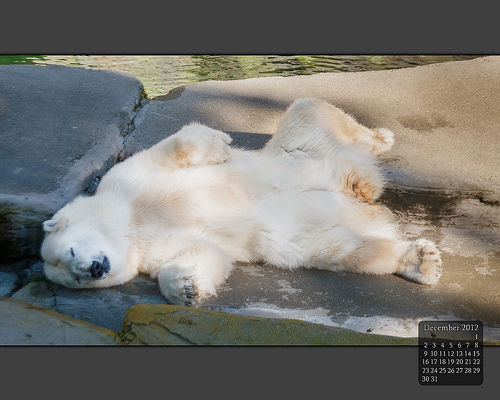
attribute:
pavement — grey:
[2, 55, 499, 347]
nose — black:
[72, 249, 102, 280]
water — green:
[0, 55, 483, 102]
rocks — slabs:
[11, 53, 498, 244]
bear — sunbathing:
[27, 79, 466, 296]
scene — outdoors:
[0, 53, 499, 348]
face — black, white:
[30, 218, 122, 293]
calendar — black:
[418, 317, 483, 387]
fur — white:
[112, 127, 354, 263]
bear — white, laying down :
[37, 93, 446, 312]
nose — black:
[90, 259, 103, 278]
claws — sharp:
[180, 275, 199, 307]